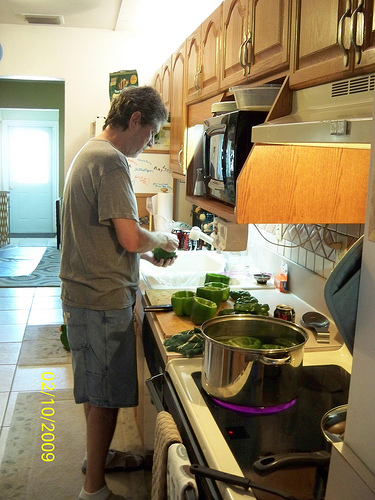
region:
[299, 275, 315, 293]
this is the wall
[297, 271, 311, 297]
the wall is white in color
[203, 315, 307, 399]
this is a cooking container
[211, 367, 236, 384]
the container is metallic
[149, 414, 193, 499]
these are some towels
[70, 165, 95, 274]
the bowl is grey in color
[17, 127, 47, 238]
this is the door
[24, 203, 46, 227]
the door is white in color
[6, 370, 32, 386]
this is the floor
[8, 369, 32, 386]
the floor is made of fish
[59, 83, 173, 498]
A man in a gray t-shirt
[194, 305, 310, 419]
A large steel pot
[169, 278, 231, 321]
Bell peppers on the counter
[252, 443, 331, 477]
A black pan handle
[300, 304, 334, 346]
A metal spoon holder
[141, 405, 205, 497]
Towels hanging on an oven handle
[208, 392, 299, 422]
A lit burner on the stove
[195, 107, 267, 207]
A black microwave oven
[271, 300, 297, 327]
An aluminum can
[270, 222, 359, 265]
Backsplash tile on the wall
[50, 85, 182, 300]
a man holding a green bell pepper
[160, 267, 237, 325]
five green bell peppers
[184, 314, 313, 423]
a silver pot on a stove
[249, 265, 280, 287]
a metal dish stopper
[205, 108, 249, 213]
a black microwave on a shelf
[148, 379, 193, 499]
two towels on a oven door handle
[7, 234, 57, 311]
a rug on the floor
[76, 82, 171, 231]
a man looking down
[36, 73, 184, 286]
a man with a green bell pepper in his hand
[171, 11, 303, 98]
wood kitchen cabinets with brass handles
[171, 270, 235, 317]
bell peppers on counter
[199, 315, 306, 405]
silver stock pot on stove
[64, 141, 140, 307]
grey cotton tee shirt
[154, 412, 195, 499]
towels hanging on stove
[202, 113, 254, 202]
black microwave in cabinet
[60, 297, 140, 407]
light blue denim shorts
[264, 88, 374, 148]
white hood stove fan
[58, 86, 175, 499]
man cutting bell peppers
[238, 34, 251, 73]
gold handles on cabinet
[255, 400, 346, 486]
black frying pan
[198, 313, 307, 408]
A stainless cooking pot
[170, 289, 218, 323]
Green bell peppers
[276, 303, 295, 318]
The top of a soda can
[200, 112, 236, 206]
A black microwave oven door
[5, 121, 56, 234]
A white door with a gold door knob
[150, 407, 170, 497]
A brown dish towel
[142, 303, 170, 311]
The handle of a knife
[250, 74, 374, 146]
A stove vent hood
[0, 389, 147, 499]
A tan colored rug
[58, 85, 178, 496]
A man with a bell pepper in his hand